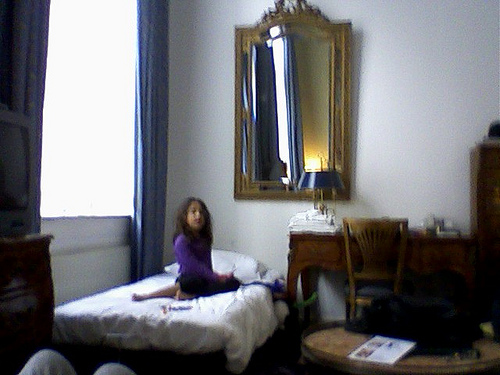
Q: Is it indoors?
A: Yes, it is indoors.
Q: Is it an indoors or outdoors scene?
A: It is indoors.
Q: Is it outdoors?
A: No, it is indoors.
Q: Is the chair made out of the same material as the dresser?
A: Yes, both the chair and the dresser are made of wood.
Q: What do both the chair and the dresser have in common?
A: The material, both the chair and the dresser are wooden.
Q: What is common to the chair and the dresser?
A: The material, both the chair and the dresser are wooden.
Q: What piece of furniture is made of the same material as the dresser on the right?
A: The chair is made of the same material as the dresser.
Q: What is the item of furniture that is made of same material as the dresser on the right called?
A: The piece of furniture is a chair.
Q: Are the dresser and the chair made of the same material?
A: Yes, both the dresser and the chair are made of wood.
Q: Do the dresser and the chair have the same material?
A: Yes, both the dresser and the chair are made of wood.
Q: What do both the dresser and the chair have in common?
A: The material, both the dresser and the chair are wooden.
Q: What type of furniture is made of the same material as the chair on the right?
A: The dresser is made of the same material as the chair.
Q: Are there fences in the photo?
A: No, there are no fences.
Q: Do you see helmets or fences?
A: No, there are no fences or helmets.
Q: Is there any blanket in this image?
A: No, there are no blankets.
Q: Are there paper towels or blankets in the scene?
A: No, there are no blankets or paper towels.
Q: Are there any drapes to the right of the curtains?
A: Yes, there are drapes to the right of the curtains.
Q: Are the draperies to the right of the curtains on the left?
A: Yes, the draperies are to the right of the curtains.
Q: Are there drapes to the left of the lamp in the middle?
A: Yes, there are drapes to the left of the lamp.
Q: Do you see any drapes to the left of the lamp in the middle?
A: Yes, there are drapes to the left of the lamp.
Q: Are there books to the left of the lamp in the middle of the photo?
A: No, there are drapes to the left of the lamp.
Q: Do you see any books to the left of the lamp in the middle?
A: No, there are drapes to the left of the lamp.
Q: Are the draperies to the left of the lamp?
A: Yes, the draperies are to the left of the lamp.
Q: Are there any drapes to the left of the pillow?
A: Yes, there are drapes to the left of the pillow.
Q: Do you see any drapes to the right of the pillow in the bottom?
A: No, the drapes are to the left of the pillow.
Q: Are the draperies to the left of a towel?
A: No, the draperies are to the left of the pillow.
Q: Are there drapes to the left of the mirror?
A: Yes, there are drapes to the left of the mirror.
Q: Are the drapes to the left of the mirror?
A: Yes, the drapes are to the left of the mirror.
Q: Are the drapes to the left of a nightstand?
A: No, the drapes are to the left of the mirror.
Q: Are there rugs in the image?
A: No, there are no rugs.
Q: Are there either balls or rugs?
A: No, there are no rugs or balls.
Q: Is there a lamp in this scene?
A: Yes, there is a lamp.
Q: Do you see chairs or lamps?
A: Yes, there is a lamp.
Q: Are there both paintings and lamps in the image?
A: No, there is a lamp but no paintings.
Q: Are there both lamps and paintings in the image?
A: No, there is a lamp but no paintings.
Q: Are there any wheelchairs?
A: No, there are no wheelchairs.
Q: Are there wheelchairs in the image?
A: No, there are no wheelchairs.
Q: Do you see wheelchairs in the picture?
A: No, there are no wheelchairs.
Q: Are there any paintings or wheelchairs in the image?
A: No, there are no wheelchairs or paintings.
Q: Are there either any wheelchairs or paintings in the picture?
A: No, there are no wheelchairs or paintings.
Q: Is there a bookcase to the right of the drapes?
A: No, there is a lamp to the right of the drapes.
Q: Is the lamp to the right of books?
A: No, the lamp is to the right of the draperies.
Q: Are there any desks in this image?
A: Yes, there is a desk.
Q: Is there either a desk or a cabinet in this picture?
A: Yes, there is a desk.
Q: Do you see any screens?
A: No, there are no screens.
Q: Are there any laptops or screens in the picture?
A: No, there are no screens or laptops.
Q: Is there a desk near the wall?
A: Yes, there is a desk near the wall.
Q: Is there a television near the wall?
A: No, there is a desk near the wall.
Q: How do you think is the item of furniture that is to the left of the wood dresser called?
A: The piece of furniture is a desk.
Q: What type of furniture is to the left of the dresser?
A: The piece of furniture is a desk.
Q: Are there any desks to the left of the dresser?
A: Yes, there is a desk to the left of the dresser.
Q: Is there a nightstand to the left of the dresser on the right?
A: No, there is a desk to the left of the dresser.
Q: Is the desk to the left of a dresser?
A: Yes, the desk is to the left of a dresser.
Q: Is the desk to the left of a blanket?
A: No, the desk is to the left of a dresser.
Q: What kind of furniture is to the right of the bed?
A: The piece of furniture is a desk.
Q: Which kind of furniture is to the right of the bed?
A: The piece of furniture is a desk.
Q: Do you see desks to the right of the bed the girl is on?
A: Yes, there is a desk to the right of the bed.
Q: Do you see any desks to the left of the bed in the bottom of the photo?
A: No, the desk is to the right of the bed.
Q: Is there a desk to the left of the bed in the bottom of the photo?
A: No, the desk is to the right of the bed.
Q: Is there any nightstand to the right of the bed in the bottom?
A: No, there is a desk to the right of the bed.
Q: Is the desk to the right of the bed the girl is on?
A: Yes, the desk is to the right of the bed.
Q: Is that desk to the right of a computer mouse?
A: No, the desk is to the right of the bed.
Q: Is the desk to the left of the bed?
A: No, the desk is to the right of the bed.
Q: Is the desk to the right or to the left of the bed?
A: The desk is to the right of the bed.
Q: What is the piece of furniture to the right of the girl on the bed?
A: The piece of furniture is a desk.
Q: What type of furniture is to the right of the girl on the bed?
A: The piece of furniture is a desk.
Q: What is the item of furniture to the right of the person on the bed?
A: The piece of furniture is a desk.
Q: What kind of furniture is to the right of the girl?
A: The piece of furniture is a desk.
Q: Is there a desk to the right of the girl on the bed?
A: Yes, there is a desk to the right of the girl.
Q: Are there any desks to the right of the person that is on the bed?
A: Yes, there is a desk to the right of the girl.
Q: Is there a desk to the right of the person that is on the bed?
A: Yes, there is a desk to the right of the girl.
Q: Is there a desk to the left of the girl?
A: No, the desk is to the right of the girl.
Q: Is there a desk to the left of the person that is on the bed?
A: No, the desk is to the right of the girl.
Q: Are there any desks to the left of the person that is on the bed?
A: No, the desk is to the right of the girl.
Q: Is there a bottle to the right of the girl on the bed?
A: No, there is a desk to the right of the girl.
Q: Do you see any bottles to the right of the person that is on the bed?
A: No, there is a desk to the right of the girl.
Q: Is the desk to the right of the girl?
A: Yes, the desk is to the right of the girl.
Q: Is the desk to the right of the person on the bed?
A: Yes, the desk is to the right of the girl.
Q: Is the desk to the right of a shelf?
A: No, the desk is to the right of the girl.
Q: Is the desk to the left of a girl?
A: No, the desk is to the right of a girl.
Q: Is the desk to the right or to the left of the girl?
A: The desk is to the right of the girl.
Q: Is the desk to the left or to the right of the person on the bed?
A: The desk is to the right of the girl.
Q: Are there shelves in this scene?
A: No, there are no shelves.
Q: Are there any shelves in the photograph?
A: No, there are no shelves.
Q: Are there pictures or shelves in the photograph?
A: No, there are no shelves or pictures.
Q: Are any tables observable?
A: Yes, there is a table.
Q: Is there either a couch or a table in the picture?
A: Yes, there is a table.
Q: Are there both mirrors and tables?
A: Yes, there are both a table and a mirror.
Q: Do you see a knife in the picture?
A: No, there are no knives.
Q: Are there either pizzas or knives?
A: No, there are no knives or pizzas.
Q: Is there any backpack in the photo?
A: Yes, there is a backpack.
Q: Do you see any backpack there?
A: Yes, there is a backpack.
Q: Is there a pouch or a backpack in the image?
A: Yes, there is a backpack.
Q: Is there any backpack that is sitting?
A: Yes, there is a backpack that is sitting.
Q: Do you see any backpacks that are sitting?
A: Yes, there is a backpack that is sitting.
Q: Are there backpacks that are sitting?
A: Yes, there is a backpack that is sitting.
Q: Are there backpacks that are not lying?
A: Yes, there is a backpack that is sitting.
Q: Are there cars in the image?
A: No, there are no cars.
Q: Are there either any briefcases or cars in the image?
A: No, there are no cars or briefcases.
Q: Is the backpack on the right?
A: Yes, the backpack is on the right of the image.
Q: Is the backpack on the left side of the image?
A: No, the backpack is on the right of the image.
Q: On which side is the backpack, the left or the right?
A: The backpack is on the right of the image.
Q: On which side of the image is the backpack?
A: The backpack is on the right of the image.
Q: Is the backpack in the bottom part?
A: Yes, the backpack is in the bottom of the image.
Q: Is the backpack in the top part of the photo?
A: No, the backpack is in the bottom of the image.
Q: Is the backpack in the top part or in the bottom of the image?
A: The backpack is in the bottom of the image.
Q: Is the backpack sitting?
A: Yes, the backpack is sitting.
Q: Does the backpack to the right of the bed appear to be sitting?
A: Yes, the backpack is sitting.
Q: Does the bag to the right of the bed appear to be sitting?
A: Yes, the backpack is sitting.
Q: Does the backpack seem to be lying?
A: No, the backpack is sitting.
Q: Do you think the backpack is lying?
A: No, the backpack is sitting.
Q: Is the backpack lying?
A: No, the backpack is sitting.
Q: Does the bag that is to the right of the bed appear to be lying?
A: No, the backpack is sitting.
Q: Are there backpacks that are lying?
A: No, there is a backpack but it is sitting.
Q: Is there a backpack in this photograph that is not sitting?
A: No, there is a backpack but it is sitting.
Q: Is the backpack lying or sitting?
A: The backpack is sitting.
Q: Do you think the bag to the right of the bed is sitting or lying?
A: The backpack is sitting.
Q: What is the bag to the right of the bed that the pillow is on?
A: The bag is a backpack.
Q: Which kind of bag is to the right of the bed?
A: The bag is a backpack.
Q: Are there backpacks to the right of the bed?
A: Yes, there is a backpack to the right of the bed.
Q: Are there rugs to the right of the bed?
A: No, there is a backpack to the right of the bed.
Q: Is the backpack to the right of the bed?
A: Yes, the backpack is to the right of the bed.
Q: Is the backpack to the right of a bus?
A: No, the backpack is to the right of the bed.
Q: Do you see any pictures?
A: No, there are no pictures.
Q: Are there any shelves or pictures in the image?
A: No, there are no pictures or shelves.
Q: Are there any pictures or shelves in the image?
A: No, there are no pictures or shelves.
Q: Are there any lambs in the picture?
A: Yes, there is a lamb.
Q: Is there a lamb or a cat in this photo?
A: Yes, there is a lamb.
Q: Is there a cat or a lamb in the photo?
A: Yes, there is a lamb.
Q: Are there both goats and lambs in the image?
A: No, there is a lamb but no goats.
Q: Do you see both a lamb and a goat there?
A: No, there is a lamb but no goats.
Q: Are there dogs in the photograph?
A: No, there are no dogs.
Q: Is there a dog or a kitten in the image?
A: No, there are no dogs or kittens.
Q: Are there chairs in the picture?
A: Yes, there is a chair.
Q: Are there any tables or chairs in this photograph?
A: Yes, there is a chair.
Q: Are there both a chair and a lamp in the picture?
A: Yes, there are both a chair and a lamp.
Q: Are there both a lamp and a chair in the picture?
A: Yes, there are both a chair and a lamp.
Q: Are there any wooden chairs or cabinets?
A: Yes, there is a wood chair.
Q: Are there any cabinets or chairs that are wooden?
A: Yes, the chair is wooden.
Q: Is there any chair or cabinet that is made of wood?
A: Yes, the chair is made of wood.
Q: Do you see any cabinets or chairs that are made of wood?
A: Yes, the chair is made of wood.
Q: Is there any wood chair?
A: Yes, there is a chair that is made of wood.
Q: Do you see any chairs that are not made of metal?
A: Yes, there is a chair that is made of wood.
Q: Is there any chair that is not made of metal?
A: Yes, there is a chair that is made of wood.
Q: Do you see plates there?
A: No, there are no plates.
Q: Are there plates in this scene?
A: No, there are no plates.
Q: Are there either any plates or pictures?
A: No, there are no plates or pictures.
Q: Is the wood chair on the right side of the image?
A: Yes, the chair is on the right of the image.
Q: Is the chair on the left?
A: No, the chair is on the right of the image.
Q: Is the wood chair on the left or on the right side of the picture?
A: The chair is on the right of the image.